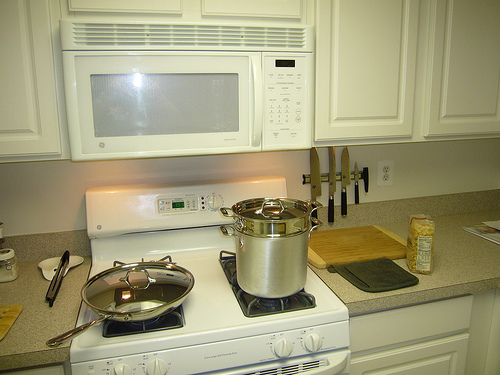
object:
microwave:
[48, 17, 316, 168]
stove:
[63, 168, 355, 375]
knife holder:
[301, 168, 369, 186]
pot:
[216, 194, 327, 240]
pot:
[219, 223, 323, 300]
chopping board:
[308, 223, 408, 272]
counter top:
[1, 183, 500, 375]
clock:
[171, 201, 185, 209]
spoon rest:
[33, 253, 86, 283]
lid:
[79, 256, 195, 317]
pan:
[41, 250, 201, 356]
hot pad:
[324, 254, 421, 296]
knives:
[305, 142, 325, 234]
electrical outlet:
[380, 164, 392, 185]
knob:
[302, 332, 325, 353]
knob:
[272, 335, 296, 359]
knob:
[142, 356, 169, 375]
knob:
[110, 361, 137, 375]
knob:
[205, 192, 225, 212]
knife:
[325, 144, 338, 228]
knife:
[339, 145, 353, 218]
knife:
[353, 159, 360, 206]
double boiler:
[217, 191, 325, 300]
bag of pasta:
[403, 210, 439, 278]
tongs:
[42, 248, 71, 309]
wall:
[0, 136, 500, 241]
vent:
[241, 355, 331, 375]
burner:
[215, 246, 321, 319]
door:
[0, 0, 63, 160]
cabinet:
[0, 0, 75, 168]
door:
[314, 0, 423, 146]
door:
[421, 0, 499, 146]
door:
[350, 333, 470, 375]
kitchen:
[1, 0, 499, 374]